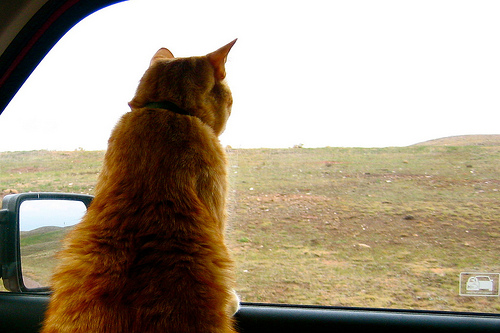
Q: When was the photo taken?
A: Daytime.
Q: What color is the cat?
A: Brown.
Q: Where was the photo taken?
A: In a car.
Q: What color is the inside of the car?
A: Black.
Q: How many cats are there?
A: One.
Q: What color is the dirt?
A: Tan.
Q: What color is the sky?
A: White.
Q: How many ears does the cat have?
A: Two.